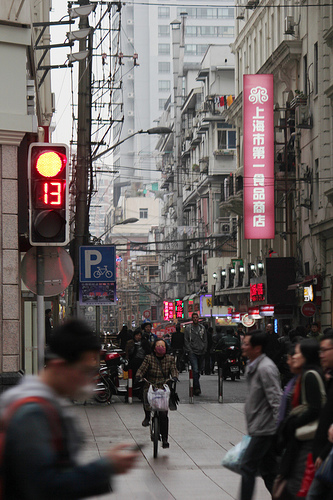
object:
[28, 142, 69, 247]
light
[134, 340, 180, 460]
man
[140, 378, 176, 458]
bike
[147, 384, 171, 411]
bag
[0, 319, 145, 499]
guy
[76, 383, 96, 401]
mask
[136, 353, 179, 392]
jacket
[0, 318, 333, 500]
people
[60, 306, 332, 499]
street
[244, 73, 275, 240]
sign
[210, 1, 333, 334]
building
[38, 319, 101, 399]
head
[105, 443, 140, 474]
hand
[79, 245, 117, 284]
sign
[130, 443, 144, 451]
phone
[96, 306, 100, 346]
pole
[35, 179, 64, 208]
walking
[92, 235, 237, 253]
wires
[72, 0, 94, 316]
pole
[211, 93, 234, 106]
clothes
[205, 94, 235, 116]
balcony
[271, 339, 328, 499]
woman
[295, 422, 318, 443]
purse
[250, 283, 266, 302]
sign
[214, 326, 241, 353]
man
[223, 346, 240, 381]
motorcycle